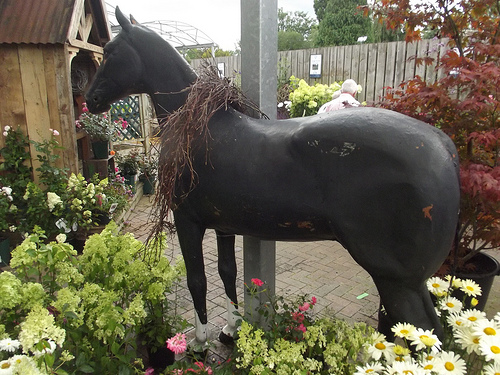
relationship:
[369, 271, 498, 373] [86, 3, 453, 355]
daisies around statue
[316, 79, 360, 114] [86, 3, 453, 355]
man behind statue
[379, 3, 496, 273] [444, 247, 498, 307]
tree in pot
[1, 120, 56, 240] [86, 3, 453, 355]
roses behind statue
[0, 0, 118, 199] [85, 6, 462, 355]
barn behind horse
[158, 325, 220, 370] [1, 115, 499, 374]
flowers in garden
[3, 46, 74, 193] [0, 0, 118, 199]
wooden wall on barn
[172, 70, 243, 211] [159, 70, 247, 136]
vines around horse's neck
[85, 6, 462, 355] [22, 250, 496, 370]
horse in garden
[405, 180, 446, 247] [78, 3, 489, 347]
paint chip on horse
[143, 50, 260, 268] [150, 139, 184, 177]
horse collar made of twigs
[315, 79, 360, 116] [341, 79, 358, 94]
man has hair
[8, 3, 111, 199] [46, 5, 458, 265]
barn in front of horse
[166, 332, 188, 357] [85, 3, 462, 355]
flowers by a horse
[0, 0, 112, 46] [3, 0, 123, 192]
roof on house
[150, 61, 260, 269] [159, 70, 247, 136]
horse collar around horse's neck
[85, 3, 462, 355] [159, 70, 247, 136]
horse has horse's neck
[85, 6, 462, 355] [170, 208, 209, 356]
horse has leg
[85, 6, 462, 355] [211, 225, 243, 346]
horse has leg